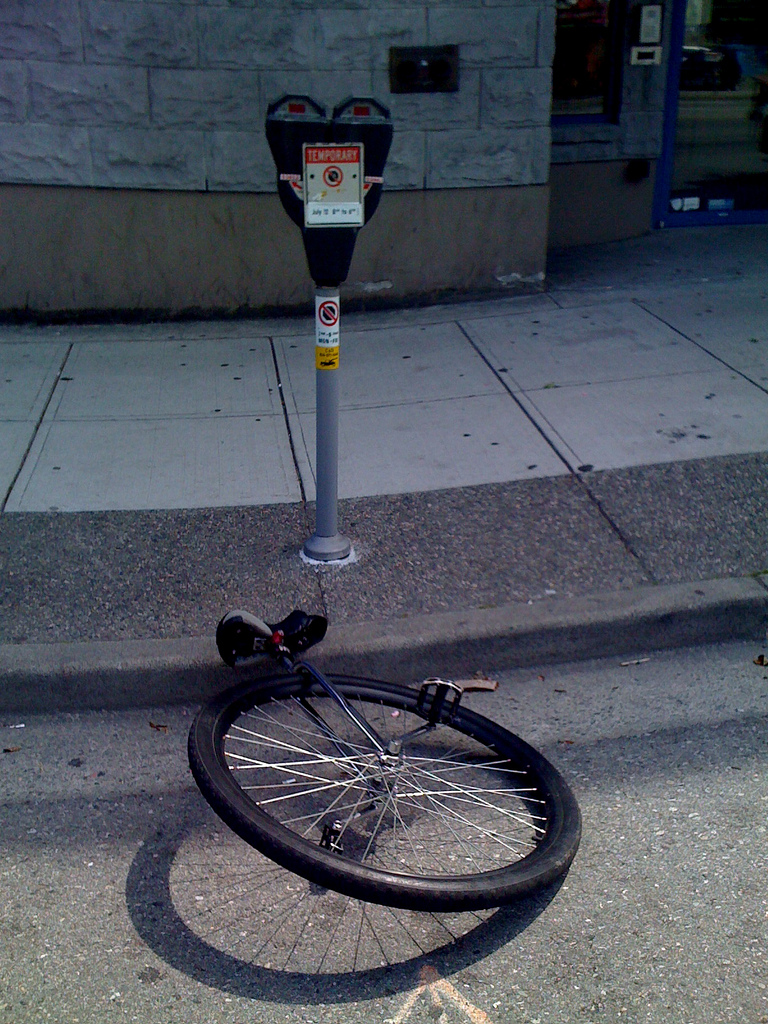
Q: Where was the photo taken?
A: On the street.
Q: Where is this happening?
A: On the street.